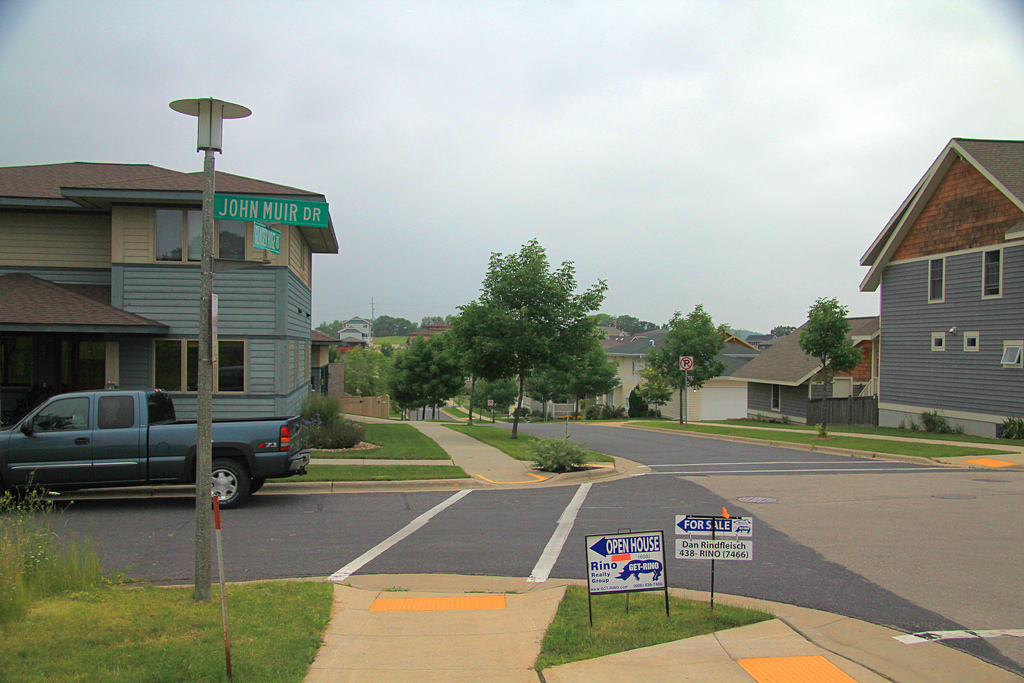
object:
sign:
[675, 507, 753, 612]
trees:
[326, 237, 609, 440]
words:
[590, 536, 661, 558]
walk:
[402, 421, 559, 484]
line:
[526, 482, 594, 582]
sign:
[585, 530, 668, 595]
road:
[0, 406, 1024, 677]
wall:
[340, 394, 389, 418]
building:
[312, 330, 391, 418]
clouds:
[0, 0, 1024, 338]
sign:
[214, 193, 330, 228]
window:
[215, 339, 245, 394]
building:
[0, 161, 340, 432]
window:
[184, 339, 198, 394]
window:
[153, 339, 185, 394]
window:
[217, 219, 248, 261]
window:
[154, 207, 187, 264]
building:
[858, 137, 1023, 439]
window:
[984, 250, 1000, 296]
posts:
[588, 590, 669, 629]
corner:
[548, 473, 1023, 683]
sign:
[679, 356, 694, 425]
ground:
[0, 579, 335, 683]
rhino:
[614, 559, 663, 581]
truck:
[0, 389, 311, 510]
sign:
[585, 528, 670, 628]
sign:
[675, 506, 753, 560]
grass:
[528, 582, 779, 672]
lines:
[324, 482, 593, 583]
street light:
[169, 97, 252, 154]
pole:
[194, 150, 215, 603]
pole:
[213, 496, 233, 682]